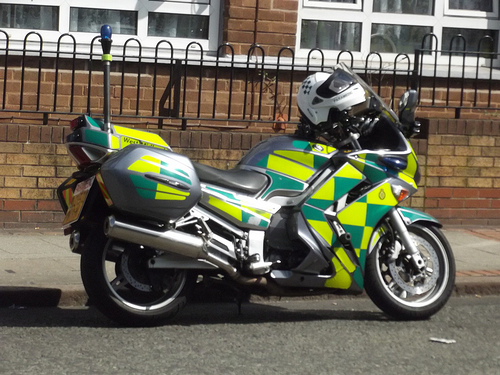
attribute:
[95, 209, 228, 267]
motorcycle exhaust — silver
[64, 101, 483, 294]
green bike — yellow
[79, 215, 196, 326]
tire — motorcycle, white, black 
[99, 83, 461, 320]
bike — street